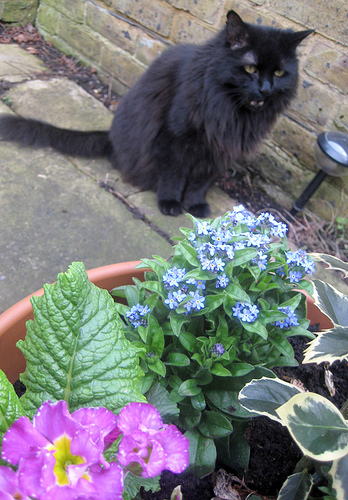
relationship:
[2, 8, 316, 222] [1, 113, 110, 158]
cat has tail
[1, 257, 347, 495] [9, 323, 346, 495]
pot has soil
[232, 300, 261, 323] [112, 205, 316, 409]
flowers on plant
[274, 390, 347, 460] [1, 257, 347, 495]
leaf in pot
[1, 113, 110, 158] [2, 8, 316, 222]
tail of cat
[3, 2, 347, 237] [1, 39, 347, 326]
wall near patio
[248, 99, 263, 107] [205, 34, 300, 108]
bell on collar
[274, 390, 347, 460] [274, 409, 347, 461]
leaf has edge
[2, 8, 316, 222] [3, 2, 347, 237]
cat near wall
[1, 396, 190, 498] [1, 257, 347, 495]
flowers in pot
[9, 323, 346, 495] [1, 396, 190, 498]
soil under flowers